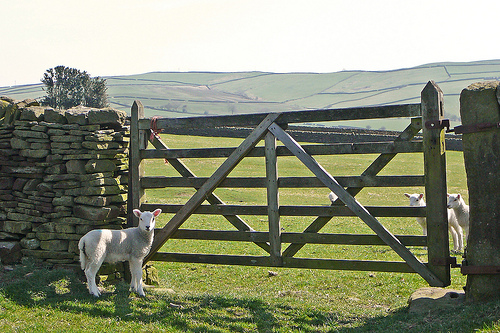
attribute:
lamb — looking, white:
[78, 209, 162, 299]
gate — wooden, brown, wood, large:
[131, 81, 451, 287]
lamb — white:
[445, 192, 470, 253]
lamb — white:
[403, 192, 464, 253]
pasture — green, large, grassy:
[130, 118, 470, 293]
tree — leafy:
[39, 66, 112, 109]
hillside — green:
[0, 59, 499, 134]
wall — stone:
[459, 81, 499, 304]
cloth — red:
[149, 117, 164, 141]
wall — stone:
[0, 99, 130, 270]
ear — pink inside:
[152, 208, 161, 216]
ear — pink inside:
[131, 209, 142, 217]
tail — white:
[78, 239, 87, 270]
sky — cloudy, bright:
[0, 1, 497, 87]